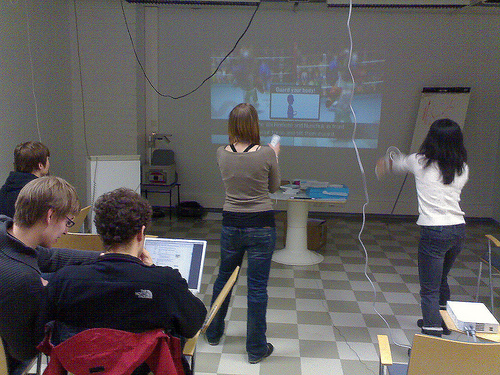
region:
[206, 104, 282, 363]
girl playing a video game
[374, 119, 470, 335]
girl playing a video game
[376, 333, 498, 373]
classroom chair and desk set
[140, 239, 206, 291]
screen of laptop computer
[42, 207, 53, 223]
a man's right ear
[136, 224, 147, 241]
a man's right ear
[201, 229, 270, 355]
woman wearing blue jeans and playing wii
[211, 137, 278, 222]
girl wearing brown sweater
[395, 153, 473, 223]
how much does she want it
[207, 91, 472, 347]
two women playing tennis when others leave them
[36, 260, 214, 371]
boy in red and black northface jacket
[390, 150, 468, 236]
i like your white shirt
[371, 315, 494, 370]
comfortable wicker with wooden arms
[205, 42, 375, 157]
basket ball game being played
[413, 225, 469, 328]
girl wearing jeans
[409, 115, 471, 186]
girl with long dark hair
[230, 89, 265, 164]
girl has brown hair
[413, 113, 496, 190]
girl has black hair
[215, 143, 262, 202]
girl has grey shirt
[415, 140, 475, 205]
girl has white shirt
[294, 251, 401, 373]
grey and white floor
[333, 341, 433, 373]
brown arm on desk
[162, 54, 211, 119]
white wall with projection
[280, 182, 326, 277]
white base on table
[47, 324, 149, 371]
man has red coat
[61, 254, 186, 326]
man has black jacket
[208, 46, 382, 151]
projector image on the wall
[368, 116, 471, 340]
girl in a white shirt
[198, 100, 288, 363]
girl in a grey shirt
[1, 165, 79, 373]
young man weaing glasses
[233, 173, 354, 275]
white table in the front of the room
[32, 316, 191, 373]
red jacket on a chair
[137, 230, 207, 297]
screen of a laptop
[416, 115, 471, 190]
long black hair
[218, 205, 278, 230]
girl's black shirt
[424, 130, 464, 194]
woman has black hair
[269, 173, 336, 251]
white table in front of women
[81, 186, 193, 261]
boy has curly hair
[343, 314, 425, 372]
brown arm on desk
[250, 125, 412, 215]
women hold white controllers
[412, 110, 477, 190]
Girl has long black hair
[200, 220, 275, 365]
A pair of blue jeans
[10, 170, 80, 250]
Blonde hair on guy's head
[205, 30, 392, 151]
Projected image on the wall